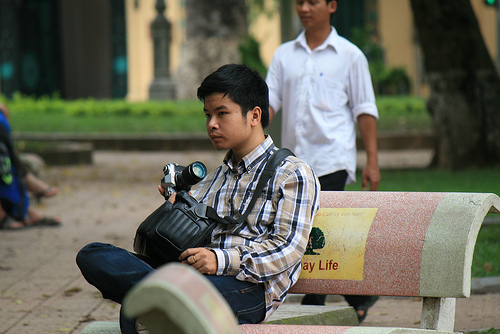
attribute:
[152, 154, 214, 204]
camera — black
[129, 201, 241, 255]
camera bag — black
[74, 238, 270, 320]
jeans — blue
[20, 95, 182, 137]
grass — gree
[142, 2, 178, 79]
statue — old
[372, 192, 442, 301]
stickering — red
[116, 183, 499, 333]
bench — cement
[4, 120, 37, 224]
dress — blue